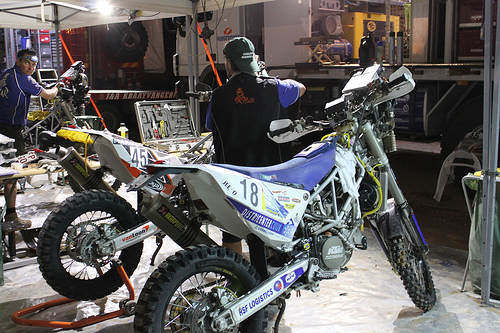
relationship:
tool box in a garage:
[122, 101, 235, 182] [72, 13, 452, 277]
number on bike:
[127, 143, 150, 173] [25, 113, 251, 302]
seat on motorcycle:
[197, 121, 360, 189] [153, 64, 412, 322]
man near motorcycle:
[204, 35, 307, 275] [129, 58, 442, 330]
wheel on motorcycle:
[128, 239, 267, 330] [129, 58, 442, 330]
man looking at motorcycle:
[0, 47, 63, 171] [129, 58, 442, 330]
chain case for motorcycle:
[205, 245, 316, 331] [129, 58, 442, 330]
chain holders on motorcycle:
[76, 219, 158, 276] [33, 123, 229, 304]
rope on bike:
[54, 128, 95, 168] [36, 85, 292, 306]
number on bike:
[234, 176, 260, 209] [123, 51, 442, 328]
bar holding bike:
[13, 257, 146, 331] [30, 82, 315, 302]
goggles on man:
[22, 52, 42, 63] [1, 42, 71, 157]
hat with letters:
[221, 34, 266, 76] [237, 48, 255, 65]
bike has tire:
[84, 59, 444, 329] [376, 191, 436, 313]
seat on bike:
[210, 158, 307, 191] [86, 30, 440, 331]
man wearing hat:
[204, 35, 307, 275] [221, 35, 263, 76]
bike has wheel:
[55, 36, 441, 332] [374, 193, 437, 310]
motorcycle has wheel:
[37, 102, 330, 299] [34, 180, 144, 297]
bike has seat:
[55, 36, 441, 332] [215, 138, 333, 192]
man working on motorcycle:
[2, 39, 61, 139] [4, 65, 114, 240]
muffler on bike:
[126, 181, 214, 242] [55, 36, 441, 332]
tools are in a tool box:
[145, 111, 172, 142] [134, 98, 214, 157]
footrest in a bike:
[296, 263, 336, 288] [55, 36, 441, 332]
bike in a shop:
[55, 36, 441, 332] [2, 1, 494, 331]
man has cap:
[202, 33, 303, 264] [217, 30, 262, 83]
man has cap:
[204, 35, 307, 275] [224, 30, 267, 83]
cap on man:
[220, 35, 266, 87] [204, 35, 307, 275]